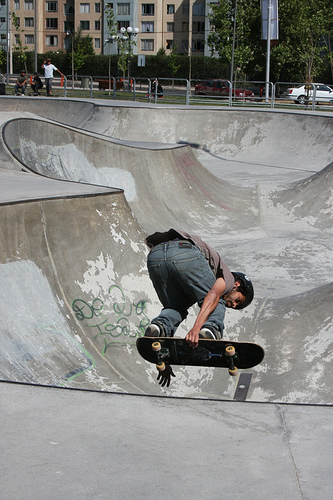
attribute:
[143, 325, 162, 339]
shoe — white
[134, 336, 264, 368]
skateboard — base, airborne, black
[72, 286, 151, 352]
grafitti — green, written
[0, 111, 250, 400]
ramp — weathered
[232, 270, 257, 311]
helmet — black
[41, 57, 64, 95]
man — watching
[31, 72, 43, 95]
man — watching, resting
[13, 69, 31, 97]
man — watching, sitting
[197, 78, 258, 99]
car — red, sedan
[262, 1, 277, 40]
sign — backwards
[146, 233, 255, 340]
man — skateboarding, performing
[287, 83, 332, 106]
car — white, parked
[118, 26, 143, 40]
light — globelight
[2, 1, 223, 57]
building — apartment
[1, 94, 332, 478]
skatepark — complex, park, enclosed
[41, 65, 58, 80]
shirt — white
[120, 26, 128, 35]
lamp — globe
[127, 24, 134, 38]
lamp — globe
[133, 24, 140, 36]
lamp — globe